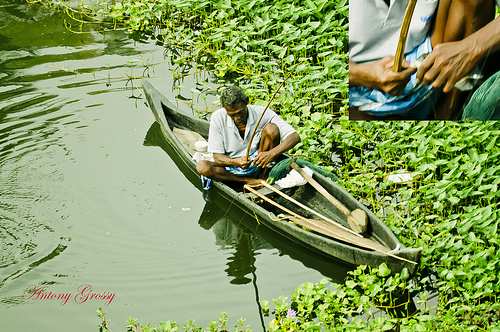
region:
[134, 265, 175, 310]
part of some water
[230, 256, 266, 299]
part of a reflection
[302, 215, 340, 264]
edge of a boat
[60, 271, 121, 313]
part of a graphic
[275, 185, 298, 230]
part of a handle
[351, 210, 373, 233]
edge of a paddle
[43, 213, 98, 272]
edge of a wave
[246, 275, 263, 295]
part of a stick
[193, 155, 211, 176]
part of a knee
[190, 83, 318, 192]
man in boat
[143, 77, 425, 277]
small green boat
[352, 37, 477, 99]
close up of man's hands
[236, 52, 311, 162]
wooden stick man is holding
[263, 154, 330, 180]
green cloth in boat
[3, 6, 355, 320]
green water boat is in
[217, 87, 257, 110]
gray hair of man in boat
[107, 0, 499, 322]
green plants growing in the water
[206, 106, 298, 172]
white and blue shirt of man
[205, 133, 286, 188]
folded legs of man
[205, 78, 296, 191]
man sitting in small boat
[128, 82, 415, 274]
man sitting in small canoe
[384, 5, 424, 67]
long stick in hand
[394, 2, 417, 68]
long curved wooden stick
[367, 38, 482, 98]
weathered hands of man holding stick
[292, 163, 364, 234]
wooden oar in canoe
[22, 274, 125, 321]
typography on bottom side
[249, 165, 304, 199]
small green bench on canoe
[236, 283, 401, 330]
green plants on top of water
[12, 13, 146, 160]
ripples in the water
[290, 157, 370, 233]
wooden boat oar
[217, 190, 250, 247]
two fishing lines in water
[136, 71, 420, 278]
fisherman fishes from canoe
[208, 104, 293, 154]
light blue short sleeved shirt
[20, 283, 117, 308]
Antony Grossy image watermark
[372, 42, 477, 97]
fisherman's hands tie knot in fishing line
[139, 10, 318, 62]
vegetation lives near water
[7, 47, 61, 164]
ripple of waves in water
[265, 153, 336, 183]
fishing net hangs in and out of canoe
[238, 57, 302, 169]
fisherman holds pole in hand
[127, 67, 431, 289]
a man in a canoe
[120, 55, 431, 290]
the canoe is green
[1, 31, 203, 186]
the water has ripples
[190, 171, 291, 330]
a reflection in the water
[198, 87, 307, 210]
the man is wearing a light colored shirt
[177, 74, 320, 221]
the man has short hair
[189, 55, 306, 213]
the man is holding a stick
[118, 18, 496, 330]
the canoe is beside the green leafy plants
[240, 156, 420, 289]
some wooden items in the canoe